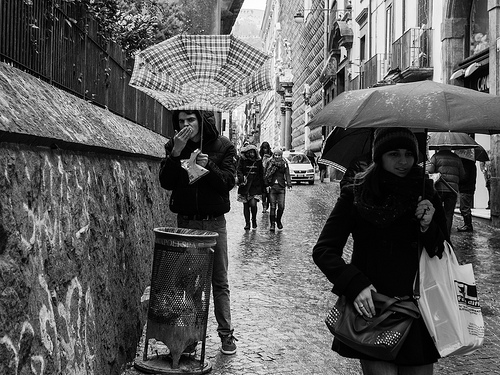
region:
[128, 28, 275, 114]
plaid umbrella turned inside out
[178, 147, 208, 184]
food wrapper in man's hand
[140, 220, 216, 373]
waste bin on brick street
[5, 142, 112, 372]
graffiti on fence wall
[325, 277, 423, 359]
purse hung on woman's shoulder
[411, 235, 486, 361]
plastic bag with purchases inside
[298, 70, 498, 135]
wet umbrella over woman's head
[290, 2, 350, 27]
street lamp anchored to wall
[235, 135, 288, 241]
three people walking down street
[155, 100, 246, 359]
man eating in front of waste bin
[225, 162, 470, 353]
road with pedestrians on it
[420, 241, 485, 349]
bag in woman's arm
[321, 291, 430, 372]
bag on woman's shoulder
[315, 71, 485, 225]
umbrella in woman's hand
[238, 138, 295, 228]
people walking in group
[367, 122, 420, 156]
hat on the woman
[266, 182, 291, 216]
pants on the woman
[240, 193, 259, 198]
shirt on the woman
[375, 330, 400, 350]
decorative pattern on bag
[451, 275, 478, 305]
image on the bag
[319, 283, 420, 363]
woman's purse with metal studs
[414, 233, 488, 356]
white plastic shopping bag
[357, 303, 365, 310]
ring on woman's finger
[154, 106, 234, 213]
man putting food in his mouth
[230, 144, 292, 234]
two woman walking on the street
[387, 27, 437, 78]
balcony on building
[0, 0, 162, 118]
wrought iron fencing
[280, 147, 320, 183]
small car parked in the distance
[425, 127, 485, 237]
two people ducking under an umbrella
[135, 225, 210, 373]
metal trash basket on road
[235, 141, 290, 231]
people walking down a wet road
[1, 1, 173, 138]
metal fence on top of concrete wall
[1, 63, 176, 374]
concrete wall beside road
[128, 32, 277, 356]
man eating and holding umbrella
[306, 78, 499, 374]
woman walking down street with umbrella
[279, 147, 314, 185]
white vehicle driving on street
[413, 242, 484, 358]
white plastic bag on woman's arm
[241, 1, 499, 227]
buildings lining a street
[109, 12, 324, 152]
a plaid umbrella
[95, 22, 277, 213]
a person holding a plaid umbrella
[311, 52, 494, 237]
a woman holding a umbrella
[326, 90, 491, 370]
a woman holding a shopping bag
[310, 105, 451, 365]
a woman holding a purse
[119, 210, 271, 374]
a trash can on the ground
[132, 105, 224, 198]
a man eating chips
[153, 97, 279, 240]
a man eating food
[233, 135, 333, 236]
people walking in the road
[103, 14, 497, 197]
people holding umbrellas